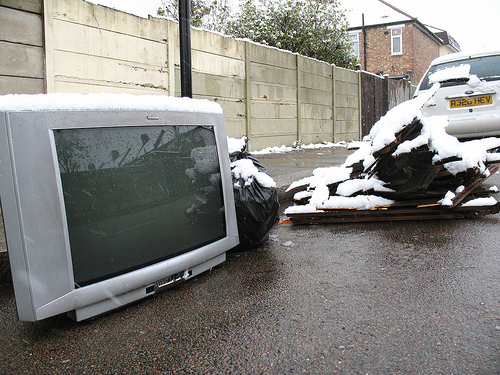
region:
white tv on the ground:
[0, 95, 240, 336]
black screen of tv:
[50, 121, 220, 282]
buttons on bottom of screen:
[152, 275, 192, 299]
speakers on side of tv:
[4, 91, 59, 333]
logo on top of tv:
[150, 113, 172, 121]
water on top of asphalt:
[315, 263, 410, 355]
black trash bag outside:
[234, 186, 282, 236]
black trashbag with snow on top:
[224, 115, 285, 249]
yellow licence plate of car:
[448, 93, 492, 108]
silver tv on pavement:
[0, 119, 255, 303]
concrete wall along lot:
[0, 56, 402, 156]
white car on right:
[388, 37, 498, 146]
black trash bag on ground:
[227, 167, 297, 249]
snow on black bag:
[227, 153, 278, 186]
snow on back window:
[413, 58, 480, 106]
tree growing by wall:
[229, 3, 359, 65]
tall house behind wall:
[357, 6, 446, 81]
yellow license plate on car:
[437, 87, 491, 109]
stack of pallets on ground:
[311, 117, 484, 224]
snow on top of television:
[4, 81, 225, 123]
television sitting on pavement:
[2, 81, 240, 338]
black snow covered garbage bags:
[217, 134, 292, 259]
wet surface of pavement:
[332, 234, 487, 373]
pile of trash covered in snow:
[285, 104, 497, 240]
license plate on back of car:
[440, 92, 497, 109]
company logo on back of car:
[458, 85, 482, 97]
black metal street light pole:
[174, 0, 199, 94]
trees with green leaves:
[229, 2, 366, 70]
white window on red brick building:
[380, 19, 410, 61]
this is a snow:
[43, 85, 199, 111]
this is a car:
[430, 55, 498, 106]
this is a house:
[360, 20, 420, 66]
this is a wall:
[28, 20, 165, 85]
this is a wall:
[223, 37, 338, 132]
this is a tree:
[240, 5, 341, 47]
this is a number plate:
[453, 95, 498, 108]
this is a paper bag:
[240, 160, 285, 248]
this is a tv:
[14, 96, 236, 292]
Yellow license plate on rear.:
[444, 90, 497, 111]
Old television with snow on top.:
[0, 96, 240, 317]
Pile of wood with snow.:
[296, 118, 491, 243]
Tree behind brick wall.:
[289, 3, 346, 58]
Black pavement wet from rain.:
[342, 285, 413, 366]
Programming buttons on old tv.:
[137, 265, 196, 295]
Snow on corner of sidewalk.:
[269, 142, 344, 160]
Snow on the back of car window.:
[424, 61, 495, 92]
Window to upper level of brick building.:
[388, 25, 407, 56]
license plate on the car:
[443, 90, 498, 116]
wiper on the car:
[430, 74, 472, 86]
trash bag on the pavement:
[229, 134, 286, 247]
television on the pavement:
[0, 107, 278, 334]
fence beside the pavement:
[10, 0, 418, 151]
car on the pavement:
[407, 48, 498, 135]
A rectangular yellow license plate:
[440, 83, 495, 113]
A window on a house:
[380, 15, 405, 60]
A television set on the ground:
[0, 76, 242, 331]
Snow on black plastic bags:
[220, 121, 290, 256]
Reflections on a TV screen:
[47, 115, 232, 285]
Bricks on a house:
[340, 15, 445, 90]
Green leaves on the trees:
[152, 0, 363, 72]